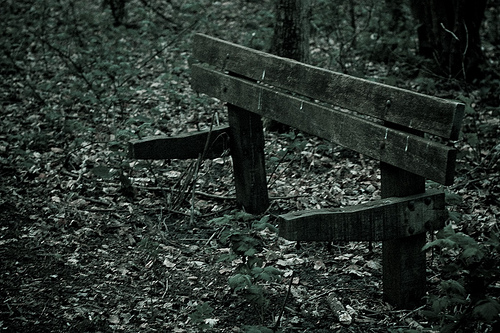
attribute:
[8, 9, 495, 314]
woods — has a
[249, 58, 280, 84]
mark — white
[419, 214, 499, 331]
plant — small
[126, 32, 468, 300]
bench — wooden, by the, wood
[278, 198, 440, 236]
bench — wooden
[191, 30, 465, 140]
slats — wooden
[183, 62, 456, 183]
slats — wooden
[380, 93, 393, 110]
lag bolt — metal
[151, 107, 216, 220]
stick — tall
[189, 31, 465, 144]
slat — wooden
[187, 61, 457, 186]
slat — wooden